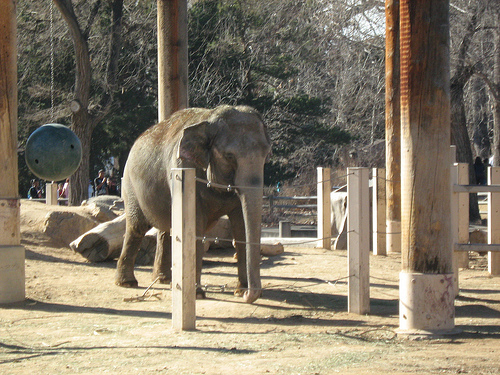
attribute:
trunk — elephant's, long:
[236, 155, 266, 302]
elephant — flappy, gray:
[110, 103, 274, 303]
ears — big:
[175, 107, 274, 169]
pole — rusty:
[396, 0, 456, 339]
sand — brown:
[1, 235, 499, 373]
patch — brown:
[140, 102, 270, 149]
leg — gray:
[114, 197, 151, 288]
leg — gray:
[195, 217, 205, 298]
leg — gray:
[229, 204, 248, 298]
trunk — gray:
[235, 163, 265, 303]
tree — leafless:
[298, 48, 383, 168]